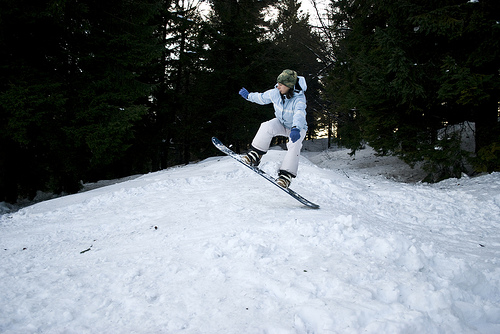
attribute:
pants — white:
[248, 118, 310, 175]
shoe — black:
[273, 162, 295, 188]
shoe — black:
[240, 145, 262, 170]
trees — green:
[4, 5, 164, 179]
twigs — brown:
[64, 220, 106, 274]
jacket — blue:
[248, 75, 306, 127]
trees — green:
[2, 7, 498, 179]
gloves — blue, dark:
[238, 89, 303, 139]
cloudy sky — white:
[300, 2, 332, 27]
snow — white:
[86, 167, 437, 331]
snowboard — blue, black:
[209, 124, 324, 216]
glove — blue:
[238, 86, 248, 99]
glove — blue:
[290, 125, 300, 141]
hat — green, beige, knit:
[272, 67, 303, 89]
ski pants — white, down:
[245, 113, 327, 186]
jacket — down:
[246, 75, 307, 132]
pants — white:
[252, 115, 307, 178]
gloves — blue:
[233, 83, 303, 140]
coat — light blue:
[242, 83, 318, 131]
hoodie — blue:
[290, 71, 313, 98]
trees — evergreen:
[51, 20, 474, 140]